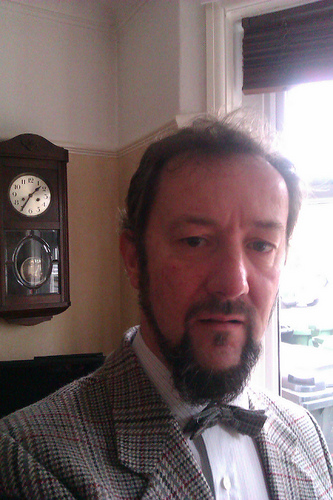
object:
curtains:
[241, 0, 332, 95]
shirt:
[134, 336, 270, 497]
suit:
[1, 323, 332, 499]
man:
[58, 87, 328, 497]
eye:
[245, 237, 277, 255]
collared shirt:
[130, 327, 271, 499]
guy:
[1, 114, 331, 498]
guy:
[137, 116, 288, 399]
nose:
[201, 239, 266, 299]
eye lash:
[257, 239, 274, 246]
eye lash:
[185, 234, 205, 242]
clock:
[0, 132, 71, 320]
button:
[221, 474, 232, 491]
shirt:
[129, 331, 282, 497]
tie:
[183, 388, 272, 447]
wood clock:
[2, 130, 70, 316]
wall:
[7, 18, 115, 356]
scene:
[74, 23, 311, 336]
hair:
[118, 113, 274, 214]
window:
[202, 0, 332, 461]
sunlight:
[278, 85, 331, 384]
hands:
[20, 195, 30, 210]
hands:
[30, 187, 40, 195]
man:
[0, 100, 332, 498]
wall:
[19, 34, 141, 119]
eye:
[175, 234, 209, 249]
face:
[9, 174, 51, 217]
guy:
[55, 157, 319, 442]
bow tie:
[183, 402, 268, 440]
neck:
[136, 324, 240, 414]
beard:
[137, 256, 264, 408]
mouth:
[198, 311, 244, 328]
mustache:
[177, 298, 258, 314]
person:
[28, 125, 323, 497]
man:
[11, 83, 319, 499]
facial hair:
[136, 294, 265, 404]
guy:
[95, 143, 290, 408]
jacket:
[86, 384, 315, 483]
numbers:
[27, 206, 42, 214]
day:
[284, 152, 332, 382]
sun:
[282, 144, 331, 191]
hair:
[138, 144, 307, 179]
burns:
[135, 240, 173, 358]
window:
[267, 147, 332, 398]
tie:
[181, 402, 274, 445]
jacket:
[71, 398, 161, 487]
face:
[143, 156, 290, 395]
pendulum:
[13, 242, 55, 288]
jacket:
[77, 394, 150, 460]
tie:
[181, 394, 280, 453]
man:
[119, 146, 307, 388]